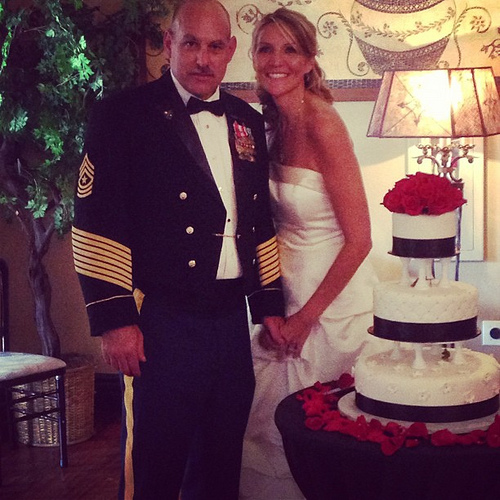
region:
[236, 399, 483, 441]
red petals on black table cloth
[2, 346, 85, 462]
black legs of a chair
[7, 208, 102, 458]
basket with fake tree in it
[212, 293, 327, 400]
two hands being held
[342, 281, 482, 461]
white and black wedding cake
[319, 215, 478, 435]
three tiers of a cake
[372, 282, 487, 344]
white cake with black trimming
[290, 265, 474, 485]
petals around a cake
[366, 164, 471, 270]
roses on top of a cake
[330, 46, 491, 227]
a lamp bhind a cake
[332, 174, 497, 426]
three tiered wedding cake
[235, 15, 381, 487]
bride with blonde hair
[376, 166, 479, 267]
cake with rose topping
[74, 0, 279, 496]
groom wearing a uniform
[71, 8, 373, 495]
bride and groom holding hands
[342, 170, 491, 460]
white and navy wedding cake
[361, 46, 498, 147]
light brown lamp shade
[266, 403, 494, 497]
table with rose petals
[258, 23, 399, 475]
woman in a strapless wedding dress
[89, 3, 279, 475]
balding man in a uniform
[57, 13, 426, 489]
man and woman posing together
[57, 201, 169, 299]
row of golden stripes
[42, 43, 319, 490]
man wearing a uniform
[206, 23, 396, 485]
woman wearing a wedding dress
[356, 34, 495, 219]
brightly lit decorative lamp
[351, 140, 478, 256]
red flowers on top of a cake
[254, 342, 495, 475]
flower petals around a cake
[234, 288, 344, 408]
two hands holding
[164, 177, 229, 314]
small silver buttons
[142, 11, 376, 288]
Woman and man posing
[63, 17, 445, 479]
Husband and wife on wedding day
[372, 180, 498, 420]
Wedding cake on table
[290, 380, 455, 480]
Rose petals on table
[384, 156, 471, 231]
Roses on top of the cake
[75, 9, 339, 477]
Man wearing a military uniform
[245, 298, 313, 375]
Couple holding hands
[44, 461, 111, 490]
Dark wooden board flooring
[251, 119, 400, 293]
Strapless dress on the woman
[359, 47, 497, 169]
Light illuminated on wall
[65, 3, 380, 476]
couple just got married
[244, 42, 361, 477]
woman wearing white dress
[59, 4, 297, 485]
man wearing a suit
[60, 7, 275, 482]
man wearing black bow tie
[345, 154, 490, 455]
black and white cake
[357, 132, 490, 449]
cake with 3 tiers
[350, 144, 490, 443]
cake with flowers on top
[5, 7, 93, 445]
tree in wicker basket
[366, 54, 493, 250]
lamp on the wall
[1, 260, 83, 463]
chair next to tree